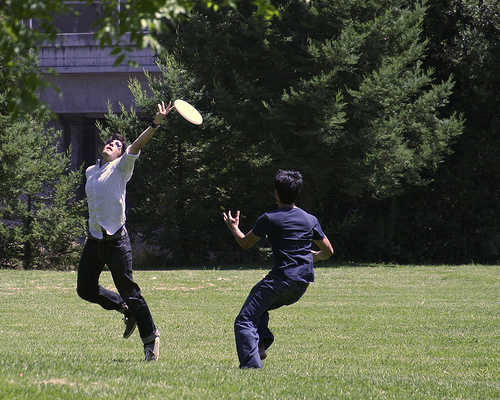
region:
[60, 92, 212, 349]
man about to catch a frisbee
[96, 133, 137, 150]
man wearing black sunglasses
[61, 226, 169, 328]
man wearing black pants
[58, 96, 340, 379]
two men playing frisbee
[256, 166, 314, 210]
man with black hair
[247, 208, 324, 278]
man wearing a black shirt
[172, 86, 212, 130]
a white fribee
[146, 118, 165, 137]
man wearing a black watch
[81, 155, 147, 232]
a white button-down shirt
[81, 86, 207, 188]
man with his arm extended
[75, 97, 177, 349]
young man is jumpin up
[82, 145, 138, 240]
young man is wearing a long sleeve shirt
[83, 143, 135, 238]
the shirt is white in color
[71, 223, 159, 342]
the young man is wearing black pants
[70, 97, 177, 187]
the young man is reaching for a frisbee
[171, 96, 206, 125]
the frisbee is in the air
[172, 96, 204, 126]
the frisbee is yellow in color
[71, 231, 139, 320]
the man's knee is bent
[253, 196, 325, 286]
the young man is wearing a short sleeve shirt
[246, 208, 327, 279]
the shirt s black in color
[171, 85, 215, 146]
A flying disc is in the air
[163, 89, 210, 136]
Flying disc is white in color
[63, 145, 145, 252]
Man is wearing a white dress shirt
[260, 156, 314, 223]
Man has dark colored hair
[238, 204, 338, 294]
Man is wearing a dark blue shirt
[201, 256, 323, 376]
Man is wearing dark blue pants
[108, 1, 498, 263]
Trees are in the background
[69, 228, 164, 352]
Man is wearing jeans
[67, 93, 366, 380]
Two men in the foreground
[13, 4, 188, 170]
A building is in the background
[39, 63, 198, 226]
man catching a frisfee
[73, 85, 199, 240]
man wearing a white shirt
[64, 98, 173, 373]
man wearing black jeans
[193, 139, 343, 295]
man runs in a field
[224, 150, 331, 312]
man wearing a black t shirt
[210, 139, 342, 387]
man wearing black pants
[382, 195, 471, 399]
grassy field with trees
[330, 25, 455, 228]
green trees in a field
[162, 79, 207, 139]
frisbee flying in the air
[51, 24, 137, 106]
building next to a field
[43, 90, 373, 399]
two people in a field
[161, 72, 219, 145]
a yellow frisbee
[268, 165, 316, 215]
a man with black hair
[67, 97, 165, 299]
a man wearing a white shirt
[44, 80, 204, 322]
a man trying to catch a frisbee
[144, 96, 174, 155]
a man wearing wrist watch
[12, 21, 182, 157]
a concrete bridge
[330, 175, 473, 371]
a field of green grass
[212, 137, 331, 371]
a man wearing blue clothes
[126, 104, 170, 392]
a man wearing brown shoes